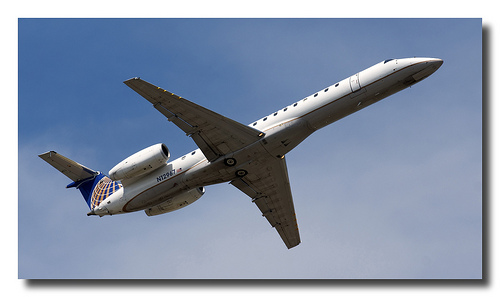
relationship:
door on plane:
[347, 72, 362, 93] [33, 45, 448, 252]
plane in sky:
[33, 45, 448, 252] [16, 16, 481, 280]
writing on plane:
[154, 167, 175, 180] [33, 45, 448, 252]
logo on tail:
[90, 175, 123, 210] [43, 148, 138, 215]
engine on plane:
[108, 138, 170, 186] [33, 45, 448, 252]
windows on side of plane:
[248, 79, 339, 125] [39, 54, 442, 244]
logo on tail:
[88, 173, 119, 208] [40, 149, 130, 216]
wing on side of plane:
[123, 76, 267, 166] [33, 45, 448, 252]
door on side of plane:
[347, 72, 362, 94] [33, 45, 448, 252]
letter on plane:
[155, 174, 163, 181] [33, 45, 448, 252]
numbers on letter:
[161, 168, 180, 180] [155, 174, 163, 181]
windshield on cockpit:
[377, 57, 395, 63] [384, 53, 394, 66]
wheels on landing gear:
[225, 156, 246, 179] [213, 154, 263, 185]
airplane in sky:
[38, 56, 443, 248] [16, 16, 481, 280]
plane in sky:
[38, 56, 444, 251] [16, 16, 481, 280]